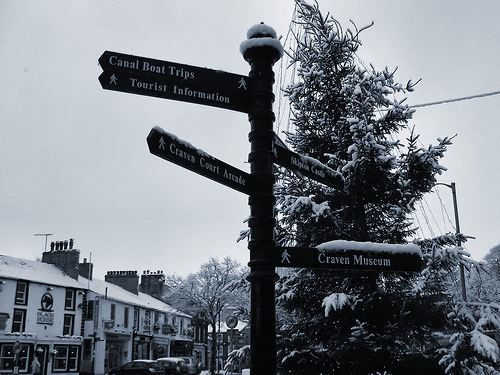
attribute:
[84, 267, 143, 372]
building — white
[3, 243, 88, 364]
building — white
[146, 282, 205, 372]
building — white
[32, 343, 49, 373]
door — black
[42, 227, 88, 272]
chimney — bricked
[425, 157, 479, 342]
pole — electric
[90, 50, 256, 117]
sign — pointing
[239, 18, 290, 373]
pole — brown, wooden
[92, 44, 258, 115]
sign — black, white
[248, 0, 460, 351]
tree — fir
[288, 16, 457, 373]
tree — leafless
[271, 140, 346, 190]
sign — pointing